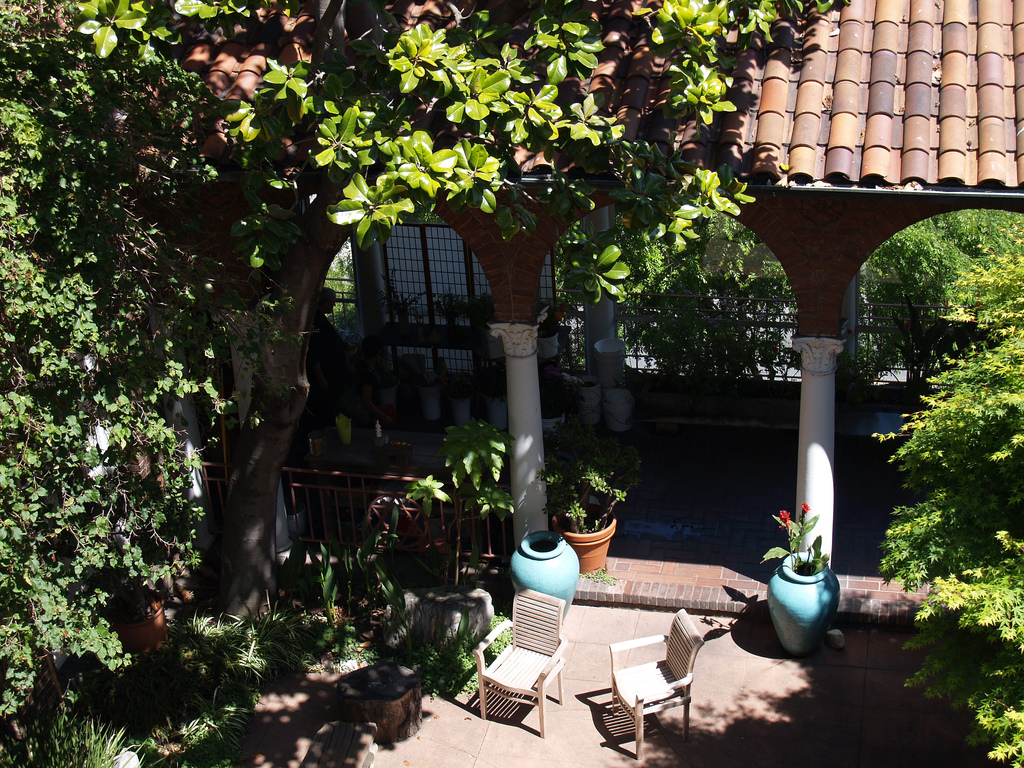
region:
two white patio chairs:
[469, 587, 716, 758]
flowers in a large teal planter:
[770, 508, 841, 652]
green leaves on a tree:
[308, 18, 717, 246]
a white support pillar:
[494, 312, 559, 560]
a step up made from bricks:
[567, 572, 765, 621]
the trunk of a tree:
[216, 389, 274, 605]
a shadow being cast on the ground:
[462, 679, 557, 741]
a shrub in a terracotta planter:
[545, 448, 638, 576]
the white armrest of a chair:
[607, 625, 668, 670]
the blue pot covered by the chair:
[516, 528, 584, 595]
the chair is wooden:
[472, 585, 572, 735]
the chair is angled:
[599, 604, 718, 764]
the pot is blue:
[756, 553, 833, 652]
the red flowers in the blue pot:
[760, 495, 833, 578]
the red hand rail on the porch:
[274, 463, 506, 562]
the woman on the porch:
[340, 325, 399, 433]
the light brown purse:
[333, 382, 376, 430]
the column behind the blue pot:
[791, 335, 845, 563]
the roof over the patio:
[647, 0, 1021, 193]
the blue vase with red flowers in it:
[756, 503, 864, 674]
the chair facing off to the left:
[602, 612, 735, 746]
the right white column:
[770, 312, 882, 597]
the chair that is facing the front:
[463, 584, 577, 734]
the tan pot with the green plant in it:
[548, 439, 640, 588]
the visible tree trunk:
[144, 237, 359, 658]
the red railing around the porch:
[216, 436, 543, 589]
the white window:
[351, 196, 552, 438]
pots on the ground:
[477, 456, 680, 638]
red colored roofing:
[100, 3, 1015, 204]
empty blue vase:
[505, 527, 582, 625]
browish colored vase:
[546, 515, 622, 580]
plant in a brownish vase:
[533, 426, 633, 531]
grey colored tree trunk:
[196, 205, 361, 638]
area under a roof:
[187, 373, 1022, 623]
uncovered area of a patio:
[274, 588, 1020, 766]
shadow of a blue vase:
[724, 597, 800, 667]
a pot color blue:
[753, 497, 850, 668]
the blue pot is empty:
[507, 521, 585, 606]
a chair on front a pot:
[456, 515, 582, 735]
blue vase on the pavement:
[763, 551, 869, 668]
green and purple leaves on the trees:
[109, 411, 187, 504]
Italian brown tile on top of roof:
[792, 35, 976, 141]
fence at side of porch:
[610, 263, 911, 404]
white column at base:
[779, 315, 857, 629]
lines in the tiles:
[770, 667, 919, 716]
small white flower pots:
[350, 347, 573, 446]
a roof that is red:
[763, 34, 979, 194]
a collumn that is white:
[766, 341, 859, 563]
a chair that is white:
[561, 601, 704, 744]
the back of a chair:
[652, 622, 710, 677]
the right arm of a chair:
[596, 628, 660, 657]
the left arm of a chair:
[629, 677, 705, 712]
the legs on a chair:
[599, 710, 692, 765]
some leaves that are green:
[430, 423, 538, 528]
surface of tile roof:
[730, 2, 1022, 190]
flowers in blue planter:
[762, 503, 839, 662]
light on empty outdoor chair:
[608, 609, 704, 759]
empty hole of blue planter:
[512, 531, 579, 604]